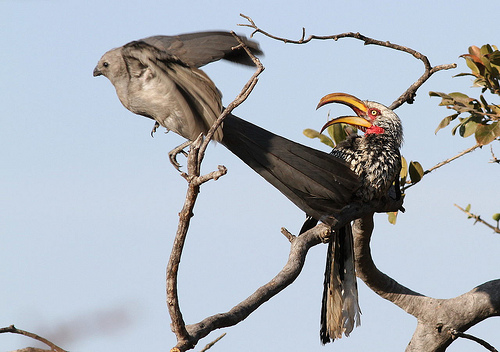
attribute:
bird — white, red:
[314, 91, 413, 343]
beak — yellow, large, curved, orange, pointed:
[314, 91, 373, 136]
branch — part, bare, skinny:
[233, 6, 459, 114]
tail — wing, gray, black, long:
[318, 221, 366, 350]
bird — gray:
[91, 27, 378, 226]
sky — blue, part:
[0, 2, 499, 351]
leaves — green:
[425, 42, 500, 243]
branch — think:
[162, 31, 268, 352]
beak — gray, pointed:
[90, 64, 104, 80]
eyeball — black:
[101, 59, 111, 71]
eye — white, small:
[369, 108, 380, 118]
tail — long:
[220, 99, 379, 230]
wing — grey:
[138, 29, 266, 73]